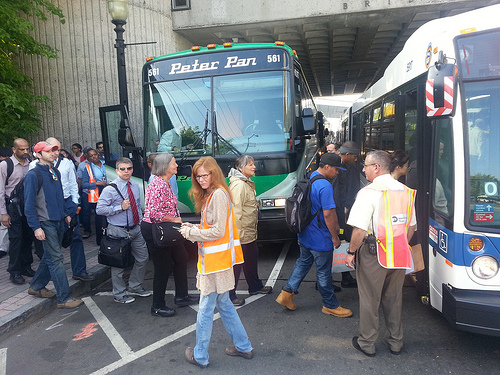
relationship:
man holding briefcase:
[100, 157, 150, 303] [98, 184, 131, 269]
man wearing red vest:
[343, 150, 416, 357] [362, 180, 418, 277]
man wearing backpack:
[277, 154, 355, 320] [285, 174, 329, 234]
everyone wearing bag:
[21, 141, 85, 313] [5, 168, 43, 223]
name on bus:
[168, 54, 260, 71] [146, 42, 323, 147]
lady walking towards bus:
[147, 150, 199, 318] [345, 32, 498, 332]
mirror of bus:
[282, 109, 343, 159] [135, 33, 349, 254]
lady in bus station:
[174, 153, 259, 364] [0, 1, 498, 372]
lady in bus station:
[147, 150, 199, 318] [0, 1, 498, 372]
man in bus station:
[277, 154, 355, 318] [0, 1, 498, 372]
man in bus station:
[343, 150, 416, 357] [0, 1, 498, 372]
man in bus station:
[100, 157, 150, 303] [0, 1, 498, 372]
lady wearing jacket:
[170, 153, 248, 355] [171, 191, 259, 261]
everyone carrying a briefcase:
[13, 138, 199, 339] [98, 184, 131, 269]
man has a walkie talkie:
[343, 150, 416, 357] [364, 230, 380, 252]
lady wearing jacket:
[174, 153, 259, 364] [178, 185, 246, 276]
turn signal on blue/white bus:
[465, 230, 483, 253] [336, 2, 500, 337]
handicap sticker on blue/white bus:
[435, 229, 447, 254] [336, 2, 500, 337]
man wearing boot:
[277, 154, 355, 318] [272, 288, 305, 304]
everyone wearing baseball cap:
[21, 141, 85, 313] [33, 142, 59, 153]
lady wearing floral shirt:
[147, 150, 199, 318] [139, 173, 181, 228]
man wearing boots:
[352, 150, 416, 359] [273, 268, 448, 365]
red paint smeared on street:
[69, 319, 101, 344] [1, 232, 498, 372]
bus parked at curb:
[137, 38, 326, 248] [0, 274, 104, 332]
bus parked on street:
[137, 38, 326, 248] [211, 355, 482, 372]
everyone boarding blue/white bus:
[21, 141, 85, 313] [336, 2, 500, 337]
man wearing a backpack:
[277, 154, 355, 320] [282, 174, 329, 235]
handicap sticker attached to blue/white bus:
[438, 229, 447, 254] [336, 2, 499, 340]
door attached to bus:
[96, 104, 146, 156] [109, 40, 336, 315]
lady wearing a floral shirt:
[147, 150, 199, 318] [139, 173, 181, 228]